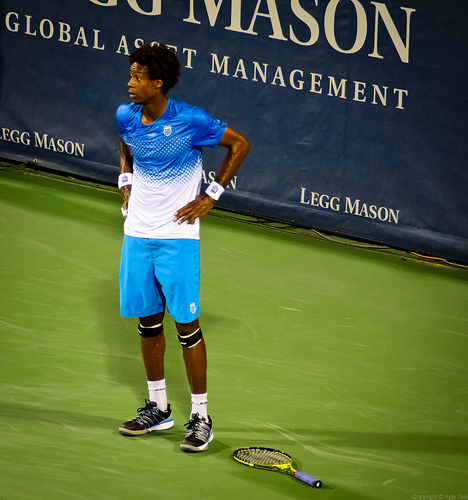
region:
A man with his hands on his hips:
[92, 37, 251, 464]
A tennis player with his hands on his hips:
[92, 24, 303, 499]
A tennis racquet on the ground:
[219, 434, 350, 498]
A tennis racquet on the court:
[229, 434, 367, 498]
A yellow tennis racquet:
[222, 436, 354, 499]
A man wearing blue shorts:
[112, 207, 212, 335]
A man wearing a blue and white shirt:
[100, 82, 238, 262]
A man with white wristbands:
[102, 167, 243, 203]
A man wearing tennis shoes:
[110, 407, 224, 465]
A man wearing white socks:
[142, 373, 216, 419]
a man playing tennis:
[94, 33, 375, 497]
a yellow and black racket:
[228, 432, 332, 493]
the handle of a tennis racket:
[288, 466, 328, 487]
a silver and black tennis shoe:
[172, 406, 224, 459]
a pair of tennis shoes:
[109, 395, 217, 459]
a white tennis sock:
[180, 390, 213, 420]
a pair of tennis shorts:
[109, 228, 217, 330]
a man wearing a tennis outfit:
[96, 47, 259, 336]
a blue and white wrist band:
[201, 174, 229, 203]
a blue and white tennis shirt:
[109, 97, 219, 244]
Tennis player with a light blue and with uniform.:
[118, 45, 248, 451]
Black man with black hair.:
[127, 45, 181, 100]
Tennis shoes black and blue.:
[119, 397, 215, 454]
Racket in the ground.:
[232, 445, 326, 489]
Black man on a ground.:
[114, 45, 247, 451]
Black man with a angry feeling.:
[125, 45, 179, 100]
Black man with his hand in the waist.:
[116, 46, 248, 451]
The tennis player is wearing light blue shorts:
[119, 231, 198, 320]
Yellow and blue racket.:
[231, 444, 318, 485]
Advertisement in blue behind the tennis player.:
[0, 0, 465, 273]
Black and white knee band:
[174, 325, 202, 349]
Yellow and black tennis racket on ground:
[232, 443, 322, 489]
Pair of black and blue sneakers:
[118, 401, 215, 451]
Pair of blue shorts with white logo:
[121, 236, 199, 320]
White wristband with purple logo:
[204, 180, 226, 198]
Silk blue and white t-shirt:
[115, 100, 225, 239]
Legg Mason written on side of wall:
[300, 184, 400, 225]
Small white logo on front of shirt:
[162, 124, 173, 136]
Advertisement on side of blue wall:
[2, 0, 415, 225]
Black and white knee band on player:
[136, 324, 164, 336]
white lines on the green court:
[259, 414, 365, 458]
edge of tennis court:
[339, 219, 415, 261]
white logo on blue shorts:
[187, 301, 209, 319]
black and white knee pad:
[163, 326, 215, 352]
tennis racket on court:
[227, 444, 336, 493]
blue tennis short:
[96, 227, 228, 322]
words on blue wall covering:
[227, 11, 388, 103]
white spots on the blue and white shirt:
[132, 135, 194, 186]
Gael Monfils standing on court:
[94, 47, 253, 466]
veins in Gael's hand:
[213, 141, 254, 181]